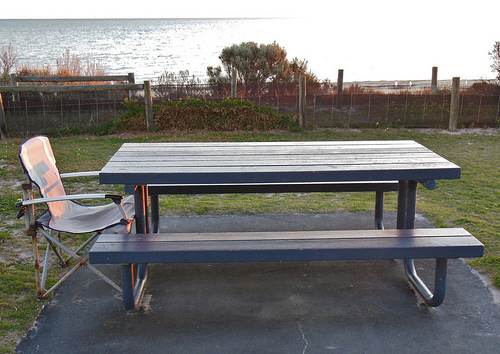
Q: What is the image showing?
A: It is showing a field.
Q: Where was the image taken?
A: It was taken at the field.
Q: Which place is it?
A: It is a field.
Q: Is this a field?
A: Yes, it is a field.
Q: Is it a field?
A: Yes, it is a field.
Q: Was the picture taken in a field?
A: Yes, it was taken in a field.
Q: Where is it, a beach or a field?
A: It is a field.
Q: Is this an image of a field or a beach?
A: It is showing a field.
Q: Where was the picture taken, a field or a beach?
A: It was taken at a field.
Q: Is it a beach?
A: No, it is a field.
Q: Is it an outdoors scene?
A: Yes, it is outdoors.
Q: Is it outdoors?
A: Yes, it is outdoors.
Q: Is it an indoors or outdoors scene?
A: It is outdoors.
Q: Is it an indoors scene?
A: No, it is outdoors.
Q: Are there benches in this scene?
A: Yes, there is a bench.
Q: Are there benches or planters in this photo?
A: Yes, there is a bench.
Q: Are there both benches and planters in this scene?
A: No, there is a bench but no planters.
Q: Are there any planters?
A: No, there are no planters.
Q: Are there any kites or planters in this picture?
A: No, there are no planters or kites.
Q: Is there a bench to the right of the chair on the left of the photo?
A: Yes, there is a bench to the right of the chair.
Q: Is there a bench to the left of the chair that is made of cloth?
A: No, the bench is to the right of the chair.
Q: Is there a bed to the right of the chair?
A: No, there is a bench to the right of the chair.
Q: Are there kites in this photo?
A: No, there are no kites.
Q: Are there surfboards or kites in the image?
A: No, there are no kites or surfboards.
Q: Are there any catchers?
A: No, there are no catchers.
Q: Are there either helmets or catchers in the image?
A: No, there are no catchers or helmets.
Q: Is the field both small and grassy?
A: Yes, the field is small and grassy.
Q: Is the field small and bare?
A: No, the field is small but grassy.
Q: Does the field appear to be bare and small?
A: No, the field is small but grassy.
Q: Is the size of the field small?
A: Yes, the field is small.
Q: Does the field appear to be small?
A: Yes, the field is small.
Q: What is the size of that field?
A: The field is small.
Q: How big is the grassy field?
A: The field is small.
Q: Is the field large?
A: No, the field is small.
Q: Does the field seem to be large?
A: No, the field is small.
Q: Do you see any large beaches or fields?
A: No, there is a field but it is small.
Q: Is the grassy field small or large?
A: The field is small.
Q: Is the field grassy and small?
A: Yes, the field is grassy and small.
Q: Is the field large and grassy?
A: No, the field is grassy but small.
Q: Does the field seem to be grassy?
A: Yes, the field is grassy.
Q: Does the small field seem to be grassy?
A: Yes, the field is grassy.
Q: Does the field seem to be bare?
A: No, the field is grassy.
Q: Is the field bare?
A: No, the field is grassy.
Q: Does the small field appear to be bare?
A: No, the field is grassy.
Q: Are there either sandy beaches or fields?
A: No, there is a field but it is grassy.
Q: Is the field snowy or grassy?
A: The field is grassy.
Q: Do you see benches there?
A: Yes, there is a bench.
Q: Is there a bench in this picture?
A: Yes, there is a bench.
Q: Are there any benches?
A: Yes, there is a bench.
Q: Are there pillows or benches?
A: Yes, there is a bench.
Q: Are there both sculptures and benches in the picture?
A: No, there is a bench but no sculptures.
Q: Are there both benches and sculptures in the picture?
A: No, there is a bench but no sculptures.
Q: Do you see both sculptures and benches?
A: No, there is a bench but no sculptures.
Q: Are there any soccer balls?
A: No, there are no soccer balls.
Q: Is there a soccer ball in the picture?
A: No, there are no soccer balls.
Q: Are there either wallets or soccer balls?
A: No, there are no soccer balls or wallets.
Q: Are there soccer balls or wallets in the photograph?
A: No, there are no soccer balls or wallets.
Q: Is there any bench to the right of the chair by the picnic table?
A: Yes, there is a bench to the right of the chair.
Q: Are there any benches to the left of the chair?
A: No, the bench is to the right of the chair.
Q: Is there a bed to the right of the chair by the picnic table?
A: No, there is a bench to the right of the chair.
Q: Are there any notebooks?
A: No, there are no notebooks.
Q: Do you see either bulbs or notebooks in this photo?
A: No, there are no notebooks or bulbs.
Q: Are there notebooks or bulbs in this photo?
A: No, there are no notebooks or bulbs.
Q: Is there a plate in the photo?
A: No, there are no plates.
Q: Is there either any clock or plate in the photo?
A: No, there are no plates or clocks.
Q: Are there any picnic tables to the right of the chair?
A: Yes, there is a picnic table to the right of the chair.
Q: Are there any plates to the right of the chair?
A: No, there is a picnic table to the right of the chair.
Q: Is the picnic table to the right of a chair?
A: Yes, the picnic table is to the right of a chair.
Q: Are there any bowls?
A: No, there are no bowls.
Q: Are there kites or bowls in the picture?
A: No, there are no bowls or kites.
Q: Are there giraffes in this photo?
A: No, there are no giraffes.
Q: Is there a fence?
A: Yes, there is a fence.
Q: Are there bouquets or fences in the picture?
A: Yes, there is a fence.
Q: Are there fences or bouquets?
A: Yes, there is a fence.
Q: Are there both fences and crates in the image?
A: No, there is a fence but no crates.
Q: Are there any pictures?
A: No, there are no pictures.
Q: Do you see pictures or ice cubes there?
A: No, there are no pictures or ice cubes.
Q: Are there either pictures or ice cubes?
A: No, there are no pictures or ice cubes.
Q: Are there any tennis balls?
A: No, there are no tennis balls.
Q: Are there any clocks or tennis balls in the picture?
A: No, there are no tennis balls or clocks.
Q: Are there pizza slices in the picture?
A: No, there are no pizza slices.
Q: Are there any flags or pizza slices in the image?
A: No, there are no pizza slices or flags.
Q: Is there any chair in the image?
A: Yes, there is a chair.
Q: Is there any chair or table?
A: Yes, there is a chair.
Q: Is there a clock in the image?
A: No, there are no clocks.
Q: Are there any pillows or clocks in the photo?
A: No, there are no clocks or pillows.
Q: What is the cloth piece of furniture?
A: The piece of furniture is a chair.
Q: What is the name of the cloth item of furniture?
A: The piece of furniture is a chair.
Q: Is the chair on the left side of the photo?
A: Yes, the chair is on the left of the image.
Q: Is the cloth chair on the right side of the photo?
A: No, the chair is on the left of the image.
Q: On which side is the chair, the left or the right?
A: The chair is on the left of the image.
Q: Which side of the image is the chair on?
A: The chair is on the left of the image.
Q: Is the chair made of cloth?
A: Yes, the chair is made of cloth.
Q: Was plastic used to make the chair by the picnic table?
A: No, the chair is made of cloth.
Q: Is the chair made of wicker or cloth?
A: The chair is made of cloth.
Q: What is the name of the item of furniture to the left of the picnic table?
A: The piece of furniture is a chair.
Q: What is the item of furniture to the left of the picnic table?
A: The piece of furniture is a chair.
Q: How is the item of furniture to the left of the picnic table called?
A: The piece of furniture is a chair.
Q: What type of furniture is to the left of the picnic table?
A: The piece of furniture is a chair.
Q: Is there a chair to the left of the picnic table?
A: Yes, there is a chair to the left of the picnic table.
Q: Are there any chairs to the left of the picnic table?
A: Yes, there is a chair to the left of the picnic table.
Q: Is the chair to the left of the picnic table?
A: Yes, the chair is to the left of the picnic table.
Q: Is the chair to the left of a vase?
A: No, the chair is to the left of the picnic table.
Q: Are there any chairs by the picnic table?
A: Yes, there is a chair by the picnic table.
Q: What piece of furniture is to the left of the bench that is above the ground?
A: The piece of furniture is a chair.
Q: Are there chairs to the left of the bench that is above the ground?
A: Yes, there is a chair to the left of the bench.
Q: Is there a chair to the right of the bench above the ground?
A: No, the chair is to the left of the bench.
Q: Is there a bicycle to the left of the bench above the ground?
A: No, there is a chair to the left of the bench.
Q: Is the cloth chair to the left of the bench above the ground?
A: Yes, the chair is to the left of the bench.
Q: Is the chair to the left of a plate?
A: No, the chair is to the left of the bench.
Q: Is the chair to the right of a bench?
A: No, the chair is to the left of a bench.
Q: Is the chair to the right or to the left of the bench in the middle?
A: The chair is to the left of the bench.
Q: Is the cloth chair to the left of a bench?
A: Yes, the chair is to the left of a bench.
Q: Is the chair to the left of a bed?
A: No, the chair is to the left of a bench.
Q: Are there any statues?
A: No, there are no statues.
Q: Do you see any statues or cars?
A: No, there are no statues or cars.